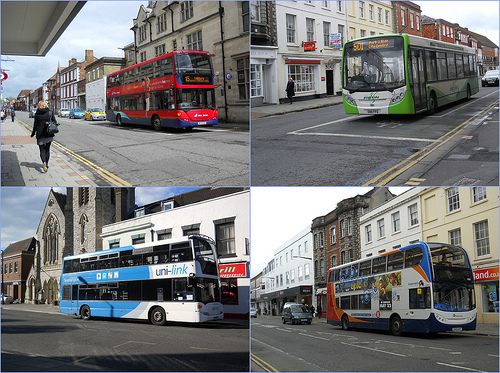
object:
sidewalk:
[2, 111, 102, 188]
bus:
[323, 238, 480, 338]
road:
[18, 110, 248, 185]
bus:
[58, 233, 225, 327]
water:
[450, 133, 490, 161]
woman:
[29, 90, 56, 178]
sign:
[294, 40, 320, 54]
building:
[252, 220, 317, 293]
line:
[287, 123, 437, 149]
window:
[284, 12, 301, 41]